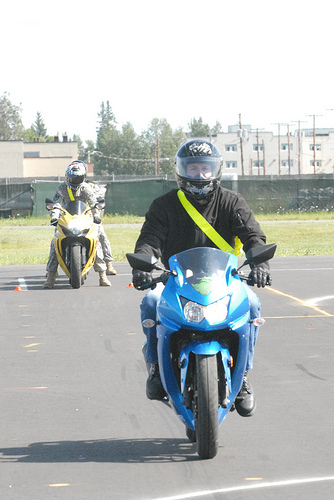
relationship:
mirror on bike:
[125, 252, 158, 272] [124, 242, 277, 460]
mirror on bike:
[245, 242, 277, 267] [124, 242, 277, 460]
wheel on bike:
[193, 353, 221, 460] [124, 242, 277, 460]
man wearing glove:
[131, 136, 273, 418] [245, 263, 271, 288]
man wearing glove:
[131, 136, 273, 418] [130, 267, 156, 291]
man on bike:
[131, 136, 273, 418] [124, 242, 277, 460]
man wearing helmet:
[131, 136, 273, 418] [173, 140, 223, 200]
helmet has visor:
[173, 140, 223, 200] [173, 156, 222, 180]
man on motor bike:
[43, 160, 114, 289] [43, 195, 105, 288]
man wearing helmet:
[43, 160, 114, 289] [65, 162, 86, 188]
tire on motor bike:
[68, 242, 83, 289] [43, 195, 105, 288]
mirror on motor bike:
[45, 197, 54, 206] [43, 195, 105, 288]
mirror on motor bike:
[95, 197, 107, 204] [43, 195, 105, 288]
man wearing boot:
[131, 136, 273, 418] [144, 363, 169, 401]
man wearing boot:
[131, 136, 273, 418] [234, 373, 257, 418]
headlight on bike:
[181, 299, 228, 325] [124, 242, 277, 460]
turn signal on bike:
[142, 317, 157, 328] [124, 242, 277, 460]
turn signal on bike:
[252, 318, 266, 328] [124, 242, 277, 460]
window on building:
[222, 143, 236, 153] [189, 123, 333, 178]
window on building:
[223, 160, 236, 171] [189, 123, 333, 178]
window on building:
[252, 143, 264, 151] [189, 123, 333, 178]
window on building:
[252, 158, 264, 166] [189, 123, 333, 178]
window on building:
[280, 140, 292, 152] [189, 123, 333, 178]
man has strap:
[131, 136, 273, 418] [176, 188, 242, 255]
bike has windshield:
[124, 242, 277, 460] [171, 244, 234, 295]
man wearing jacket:
[131, 136, 273, 418] [134, 186, 270, 264]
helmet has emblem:
[173, 140, 223, 200] [187, 141, 210, 157]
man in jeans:
[131, 136, 273, 418] [133, 277, 261, 379]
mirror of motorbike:
[125, 252, 160, 272] [125, 243, 277, 456]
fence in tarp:
[3, 173, 333, 218] [7, 177, 333, 213]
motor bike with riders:
[44, 196, 106, 289] [40, 155, 113, 291]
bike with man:
[126, 242, 277, 460] [131, 136, 273, 418]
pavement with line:
[3, 252, 323, 496] [263, 283, 332, 316]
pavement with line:
[3, 252, 323, 496] [259, 313, 332, 319]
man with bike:
[131, 136, 274, 409] [126, 242, 277, 460]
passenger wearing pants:
[45, 159, 117, 277] [44, 227, 111, 293]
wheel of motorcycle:
[189, 353, 218, 458] [127, 243, 288, 455]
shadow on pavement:
[1, 435, 188, 473] [3, 252, 323, 496]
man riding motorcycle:
[131, 136, 274, 409] [127, 243, 288, 455]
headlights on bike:
[178, 293, 240, 329] [126, 242, 277, 460]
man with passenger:
[43, 160, 112, 289] [71, 159, 116, 273]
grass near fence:
[255, 209, 333, 222] [0, 174, 331, 214]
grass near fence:
[0, 209, 334, 266] [0, 174, 331, 214]